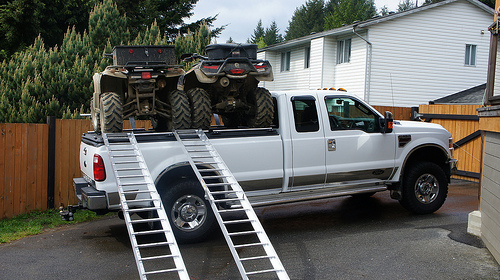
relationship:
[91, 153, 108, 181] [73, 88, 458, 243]
light on back of truck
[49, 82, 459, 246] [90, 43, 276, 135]
truck with four wheelers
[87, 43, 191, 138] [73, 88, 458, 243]
four wheeler sitting in truck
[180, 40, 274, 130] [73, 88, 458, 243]
four wheeler sitting in truck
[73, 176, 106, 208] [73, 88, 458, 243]
bumper mounted on truck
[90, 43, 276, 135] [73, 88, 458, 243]
four wheelers on back of truck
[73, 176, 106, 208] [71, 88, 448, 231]
bumper of truck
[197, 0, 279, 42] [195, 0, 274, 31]
sky with clouds